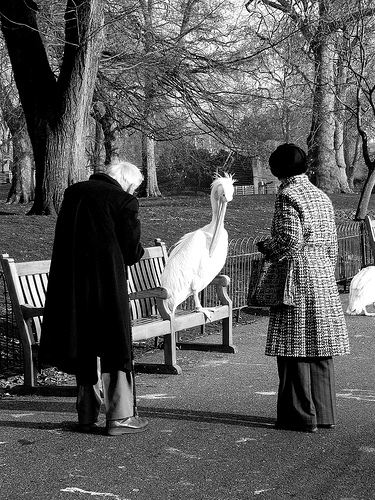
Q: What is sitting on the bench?
A: Pelican.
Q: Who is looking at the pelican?
A: Old people.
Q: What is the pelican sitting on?
A: Bench.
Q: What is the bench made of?
A: Wood.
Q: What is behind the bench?
A: Fence.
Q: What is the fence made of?
A: Metal.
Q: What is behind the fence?
A: Trees.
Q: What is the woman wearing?
A: A coat.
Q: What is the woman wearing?
A: A coat.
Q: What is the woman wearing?
A: A coat.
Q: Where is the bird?
A: On the bench.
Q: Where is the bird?
A: On the bench.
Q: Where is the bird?
A: On the bench.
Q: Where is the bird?
A: On the bench.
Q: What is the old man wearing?
A: A coat.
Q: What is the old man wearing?
A: A coat.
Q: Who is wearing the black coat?
A: The old man.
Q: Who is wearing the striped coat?
A: The woman.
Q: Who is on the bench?
A: The bird.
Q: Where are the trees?
A: Behind the fence.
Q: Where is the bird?
A: On the bench.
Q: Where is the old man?
A: By the bench.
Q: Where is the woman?
A: By the bird.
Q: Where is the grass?
A: Under the trees.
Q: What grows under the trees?
A: Grass.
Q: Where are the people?
A: By the bench.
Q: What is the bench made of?
A: Wood.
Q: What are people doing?
A: Observing.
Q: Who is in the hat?
A: A woman.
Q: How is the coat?
A: Patterned.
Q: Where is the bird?
A: On bench.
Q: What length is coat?
A: Long.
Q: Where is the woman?
A: By bird.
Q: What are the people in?
A: Outerwear.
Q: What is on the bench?
A: Large white bird.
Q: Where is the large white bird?
A: On the bench.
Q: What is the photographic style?
A: Black and white.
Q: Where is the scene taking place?
A: A park.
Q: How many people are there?
A: Two.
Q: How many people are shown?
A: Two.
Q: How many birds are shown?
A: 2.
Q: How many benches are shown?
A: One.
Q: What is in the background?
A: Trees.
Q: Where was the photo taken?
A: In a park.